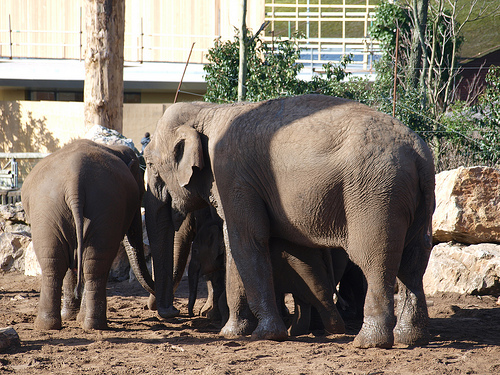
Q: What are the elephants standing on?
A: Dirt.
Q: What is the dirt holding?
A: Elephants.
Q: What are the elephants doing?
A: Standing on the dirt.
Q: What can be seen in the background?
A: A building.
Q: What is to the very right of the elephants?
A: Rocks.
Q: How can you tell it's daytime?
A: It is sunny out.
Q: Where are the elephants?
A: In an enclosure.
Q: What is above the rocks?
A: Trees.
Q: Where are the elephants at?
A: On the dirt.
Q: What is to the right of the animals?
A: The boulders.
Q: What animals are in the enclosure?
A: The elephants.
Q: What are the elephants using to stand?
A: Legs.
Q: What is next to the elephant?
A: Rocks.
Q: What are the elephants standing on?
A: Dirt.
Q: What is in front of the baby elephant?
A: A pole.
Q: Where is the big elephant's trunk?
A: Near the ground.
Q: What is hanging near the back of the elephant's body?
A: A tail.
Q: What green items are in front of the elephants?
A: Trees.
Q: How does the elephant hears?
A: With their ears.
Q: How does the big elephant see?
A: With its eye.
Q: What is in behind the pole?
A: A building.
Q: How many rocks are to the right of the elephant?
A: Two.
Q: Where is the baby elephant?
A: Hiding under the big elephant.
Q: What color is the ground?
A: Brown.